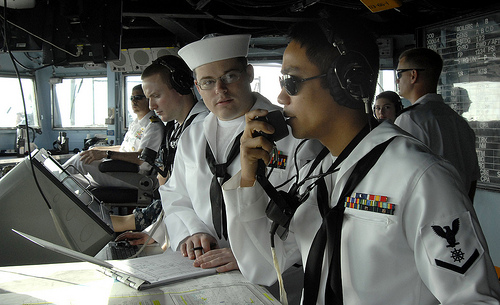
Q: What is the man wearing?
A: Glasses.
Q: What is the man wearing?
A: Sunglasses.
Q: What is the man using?
A: Walkie talkie.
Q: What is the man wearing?
A: Shirt.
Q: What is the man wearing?
A: Watch.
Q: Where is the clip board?
A: Desk.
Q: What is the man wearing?
A: Sunglasses.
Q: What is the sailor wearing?
A: Sunglasses.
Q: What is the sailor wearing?
A: Sunglasses.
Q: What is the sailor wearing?
A: Eyeglasses.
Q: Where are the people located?
A: Boat.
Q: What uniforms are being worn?
A: Sailor uniforms.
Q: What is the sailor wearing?
A: Sunglasses.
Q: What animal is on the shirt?
A: A drawing of an eagle.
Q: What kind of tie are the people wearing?
A: Loose black ties.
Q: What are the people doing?
A: Working.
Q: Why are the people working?
A: They are in the military.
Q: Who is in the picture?
A: Sailors.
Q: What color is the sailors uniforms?
A: White.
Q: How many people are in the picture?
A: Six.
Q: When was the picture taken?
A: During the day.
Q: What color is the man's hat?
A: White.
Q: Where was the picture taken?
A: On a ship.